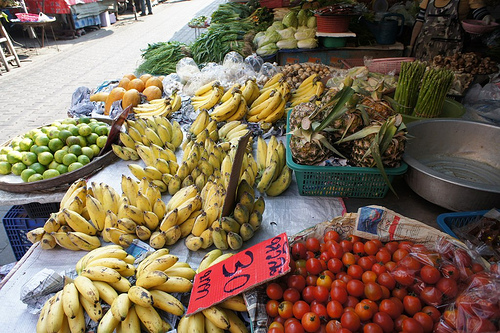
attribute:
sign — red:
[180, 228, 291, 318]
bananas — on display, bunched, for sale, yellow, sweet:
[66, 229, 102, 251]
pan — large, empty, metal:
[400, 115, 498, 217]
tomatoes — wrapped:
[328, 301, 343, 319]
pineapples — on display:
[285, 116, 347, 165]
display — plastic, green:
[286, 103, 409, 200]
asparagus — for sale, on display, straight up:
[393, 60, 426, 117]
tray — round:
[2, 115, 122, 193]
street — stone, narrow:
[1, 1, 210, 146]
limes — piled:
[39, 152, 54, 166]